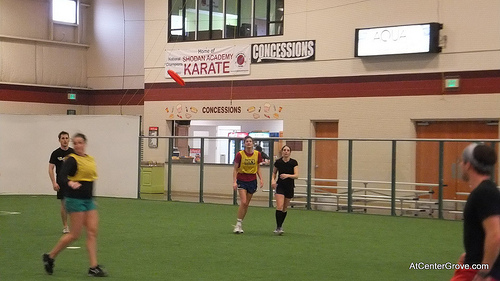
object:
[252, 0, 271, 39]
window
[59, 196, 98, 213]
shorts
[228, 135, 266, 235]
woman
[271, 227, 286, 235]
shoes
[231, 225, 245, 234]
shoes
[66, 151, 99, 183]
yellow shirt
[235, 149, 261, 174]
yellow tank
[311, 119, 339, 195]
door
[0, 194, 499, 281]
floor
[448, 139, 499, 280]
man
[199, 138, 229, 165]
window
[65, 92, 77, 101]
exit sign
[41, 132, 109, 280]
people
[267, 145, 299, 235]
people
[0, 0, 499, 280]
gym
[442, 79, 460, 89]
exit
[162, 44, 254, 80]
sign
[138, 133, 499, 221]
fence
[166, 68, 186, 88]
frisbee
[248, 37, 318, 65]
sign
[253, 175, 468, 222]
bleachers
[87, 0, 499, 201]
wall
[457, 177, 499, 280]
shirt